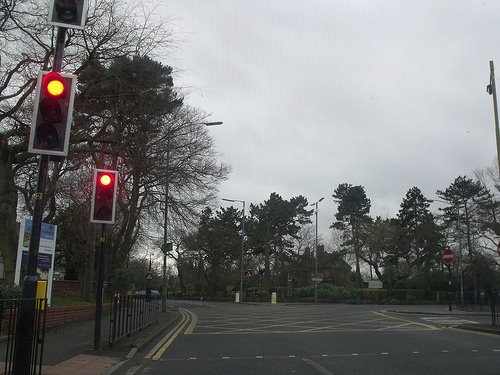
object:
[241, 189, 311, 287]
trees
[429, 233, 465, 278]
sign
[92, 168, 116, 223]
light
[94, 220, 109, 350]
pole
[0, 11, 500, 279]
sky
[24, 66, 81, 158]
raffic signal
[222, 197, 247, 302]
pole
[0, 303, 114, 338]
brick wall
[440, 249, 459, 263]
sign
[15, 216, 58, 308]
sign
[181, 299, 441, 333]
lines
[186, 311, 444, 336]
lines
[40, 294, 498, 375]
ground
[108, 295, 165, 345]
railing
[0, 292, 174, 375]
black fence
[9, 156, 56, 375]
pole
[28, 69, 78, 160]
sign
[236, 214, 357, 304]
leaves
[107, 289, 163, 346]
fence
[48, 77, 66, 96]
red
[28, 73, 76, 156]
light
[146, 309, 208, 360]
lines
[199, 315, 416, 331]
lines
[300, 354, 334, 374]
lines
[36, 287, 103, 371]
gate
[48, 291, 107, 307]
grass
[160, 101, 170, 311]
pole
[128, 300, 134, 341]
opening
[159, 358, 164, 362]
dots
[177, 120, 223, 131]
light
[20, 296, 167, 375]
sidewalk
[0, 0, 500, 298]
background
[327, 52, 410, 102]
cloud